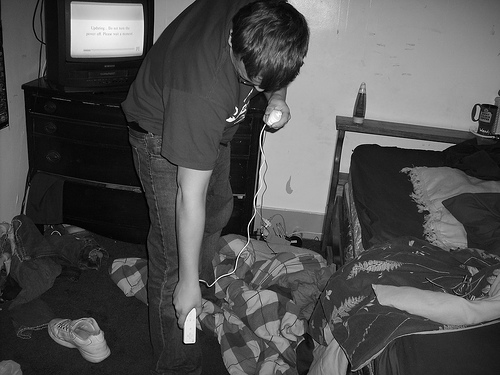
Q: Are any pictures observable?
A: No, there are no pictures.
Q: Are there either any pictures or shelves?
A: No, there are no pictures or shelves.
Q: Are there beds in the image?
A: Yes, there is a bed.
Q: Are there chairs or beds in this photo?
A: Yes, there is a bed.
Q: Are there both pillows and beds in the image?
A: Yes, there are both a bed and a pillow.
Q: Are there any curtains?
A: No, there are no curtains.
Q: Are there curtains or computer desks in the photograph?
A: No, there are no curtains or computer desks.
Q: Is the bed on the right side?
A: Yes, the bed is on the right of the image.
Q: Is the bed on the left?
A: No, the bed is on the right of the image.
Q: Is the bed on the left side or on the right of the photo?
A: The bed is on the right of the image.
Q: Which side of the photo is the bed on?
A: The bed is on the right of the image.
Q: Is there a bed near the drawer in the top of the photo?
A: Yes, there is a bed near the drawer.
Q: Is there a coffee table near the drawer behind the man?
A: No, there is a bed near the drawer.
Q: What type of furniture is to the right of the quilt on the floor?
A: The piece of furniture is a bed.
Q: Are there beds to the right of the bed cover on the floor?
A: Yes, there is a bed to the right of the comforter.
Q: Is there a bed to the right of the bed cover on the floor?
A: Yes, there is a bed to the right of the comforter.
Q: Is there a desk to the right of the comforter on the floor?
A: No, there is a bed to the right of the comforter.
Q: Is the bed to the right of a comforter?
A: Yes, the bed is to the right of a comforter.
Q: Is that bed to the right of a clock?
A: No, the bed is to the right of a comforter.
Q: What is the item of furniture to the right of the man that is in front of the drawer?
A: The piece of furniture is a bed.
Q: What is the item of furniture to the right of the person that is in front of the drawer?
A: The piece of furniture is a bed.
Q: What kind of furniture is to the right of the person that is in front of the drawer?
A: The piece of furniture is a bed.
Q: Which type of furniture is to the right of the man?
A: The piece of furniture is a bed.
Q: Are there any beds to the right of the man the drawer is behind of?
A: Yes, there is a bed to the right of the man.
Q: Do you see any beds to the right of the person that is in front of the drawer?
A: Yes, there is a bed to the right of the man.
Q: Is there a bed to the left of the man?
A: No, the bed is to the right of the man.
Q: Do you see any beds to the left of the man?
A: No, the bed is to the right of the man.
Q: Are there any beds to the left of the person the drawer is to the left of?
A: No, the bed is to the right of the man.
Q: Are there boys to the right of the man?
A: No, there is a bed to the right of the man.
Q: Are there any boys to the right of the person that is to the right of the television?
A: No, there is a bed to the right of the man.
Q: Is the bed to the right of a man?
A: Yes, the bed is to the right of a man.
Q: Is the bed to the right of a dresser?
A: No, the bed is to the right of a man.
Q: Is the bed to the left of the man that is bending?
A: No, the bed is to the right of the man.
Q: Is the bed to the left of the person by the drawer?
A: No, the bed is to the right of the man.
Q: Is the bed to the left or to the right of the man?
A: The bed is to the right of the man.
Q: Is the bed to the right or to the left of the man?
A: The bed is to the right of the man.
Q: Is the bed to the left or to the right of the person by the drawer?
A: The bed is to the right of the man.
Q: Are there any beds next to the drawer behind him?
A: Yes, there is a bed next to the drawer.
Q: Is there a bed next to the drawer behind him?
A: Yes, there is a bed next to the drawer.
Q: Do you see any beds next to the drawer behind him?
A: Yes, there is a bed next to the drawer.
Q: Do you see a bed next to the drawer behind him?
A: Yes, there is a bed next to the drawer.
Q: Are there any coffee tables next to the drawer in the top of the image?
A: No, there is a bed next to the drawer.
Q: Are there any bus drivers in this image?
A: No, there are no bus drivers.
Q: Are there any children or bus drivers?
A: No, there are no bus drivers or children.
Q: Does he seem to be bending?
A: Yes, the man is bending.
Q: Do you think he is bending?
A: Yes, the man is bending.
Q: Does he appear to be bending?
A: Yes, the man is bending.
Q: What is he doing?
A: The man is bending.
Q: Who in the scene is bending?
A: The man is bending.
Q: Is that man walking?
A: No, the man is bending.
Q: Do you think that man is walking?
A: No, the man is bending.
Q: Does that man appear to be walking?
A: No, the man is bending.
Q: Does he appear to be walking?
A: No, the man is bending.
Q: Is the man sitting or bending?
A: The man is bending.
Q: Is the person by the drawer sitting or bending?
A: The man is bending.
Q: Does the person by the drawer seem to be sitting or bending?
A: The man is bending.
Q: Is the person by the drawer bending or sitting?
A: The man is bending.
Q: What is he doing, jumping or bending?
A: The man is bending.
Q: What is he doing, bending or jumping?
A: The man is bending.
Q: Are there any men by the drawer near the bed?
A: Yes, there is a man by the drawer.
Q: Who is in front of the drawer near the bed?
A: The man is in front of the drawer.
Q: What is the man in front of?
A: The man is in front of the drawer.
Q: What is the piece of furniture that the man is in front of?
A: The piece of furniture is a drawer.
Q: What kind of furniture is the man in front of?
A: The man is in front of the drawer.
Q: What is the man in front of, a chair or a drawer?
A: The man is in front of a drawer.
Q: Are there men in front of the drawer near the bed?
A: Yes, there is a man in front of the drawer.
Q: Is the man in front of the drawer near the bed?
A: Yes, the man is in front of the drawer.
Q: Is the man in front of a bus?
A: No, the man is in front of the drawer.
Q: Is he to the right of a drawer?
A: Yes, the man is to the right of a drawer.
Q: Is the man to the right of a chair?
A: No, the man is to the right of a drawer.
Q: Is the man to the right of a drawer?
A: Yes, the man is to the right of a drawer.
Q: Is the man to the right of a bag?
A: No, the man is to the right of a drawer.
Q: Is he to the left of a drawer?
A: No, the man is to the right of a drawer.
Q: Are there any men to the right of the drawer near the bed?
A: Yes, there is a man to the right of the drawer.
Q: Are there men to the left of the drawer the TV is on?
A: No, the man is to the right of the drawer.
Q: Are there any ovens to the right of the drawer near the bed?
A: No, there is a man to the right of the drawer.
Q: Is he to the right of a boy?
A: No, the man is to the right of a drawer.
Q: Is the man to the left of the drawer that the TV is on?
A: No, the man is to the right of the drawer.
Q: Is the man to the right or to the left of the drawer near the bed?
A: The man is to the right of the drawer.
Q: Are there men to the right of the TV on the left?
A: Yes, there is a man to the right of the TV.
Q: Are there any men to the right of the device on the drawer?
A: Yes, there is a man to the right of the TV.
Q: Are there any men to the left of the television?
A: No, the man is to the right of the television.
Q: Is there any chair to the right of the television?
A: No, there is a man to the right of the television.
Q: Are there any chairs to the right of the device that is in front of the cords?
A: No, there is a man to the right of the television.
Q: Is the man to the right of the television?
A: Yes, the man is to the right of the television.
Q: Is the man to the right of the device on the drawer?
A: Yes, the man is to the right of the television.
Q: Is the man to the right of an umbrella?
A: No, the man is to the right of the television.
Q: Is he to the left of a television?
A: No, the man is to the right of a television.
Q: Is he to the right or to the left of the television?
A: The man is to the right of the television.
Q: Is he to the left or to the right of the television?
A: The man is to the right of the television.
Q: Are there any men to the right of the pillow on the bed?
A: No, the man is to the left of the pillow.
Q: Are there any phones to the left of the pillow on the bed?
A: No, there is a man to the left of the pillow.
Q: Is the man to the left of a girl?
A: No, the man is to the left of the pillow.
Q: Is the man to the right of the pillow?
A: No, the man is to the left of the pillow.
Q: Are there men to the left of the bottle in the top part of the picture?
A: Yes, there is a man to the left of the bottle.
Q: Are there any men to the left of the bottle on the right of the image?
A: Yes, there is a man to the left of the bottle.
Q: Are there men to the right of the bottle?
A: No, the man is to the left of the bottle.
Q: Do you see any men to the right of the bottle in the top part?
A: No, the man is to the left of the bottle.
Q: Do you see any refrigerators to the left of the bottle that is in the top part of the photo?
A: No, there is a man to the left of the bottle.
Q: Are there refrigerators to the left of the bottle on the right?
A: No, there is a man to the left of the bottle.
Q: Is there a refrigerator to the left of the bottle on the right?
A: No, there is a man to the left of the bottle.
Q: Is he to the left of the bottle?
A: Yes, the man is to the left of the bottle.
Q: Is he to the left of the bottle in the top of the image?
A: Yes, the man is to the left of the bottle.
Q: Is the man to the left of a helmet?
A: No, the man is to the left of the bottle.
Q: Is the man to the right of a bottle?
A: No, the man is to the left of a bottle.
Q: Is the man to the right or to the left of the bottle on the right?
A: The man is to the left of the bottle.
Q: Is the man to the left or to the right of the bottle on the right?
A: The man is to the left of the bottle.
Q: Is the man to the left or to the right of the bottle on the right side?
A: The man is to the left of the bottle.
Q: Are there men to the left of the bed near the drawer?
A: Yes, there is a man to the left of the bed.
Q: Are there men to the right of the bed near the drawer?
A: No, the man is to the left of the bed.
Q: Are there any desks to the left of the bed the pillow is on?
A: No, there is a man to the left of the bed.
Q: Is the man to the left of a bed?
A: Yes, the man is to the left of a bed.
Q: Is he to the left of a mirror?
A: No, the man is to the left of a bed.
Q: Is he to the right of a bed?
A: No, the man is to the left of a bed.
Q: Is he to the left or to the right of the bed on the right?
A: The man is to the left of the bed.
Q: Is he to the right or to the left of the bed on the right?
A: The man is to the left of the bed.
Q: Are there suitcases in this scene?
A: No, there are no suitcases.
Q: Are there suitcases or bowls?
A: No, there are no suitcases or bowls.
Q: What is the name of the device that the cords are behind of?
A: The device is a television.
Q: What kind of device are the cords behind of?
A: The cords are behind the television.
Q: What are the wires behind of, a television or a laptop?
A: The wires are behind a television.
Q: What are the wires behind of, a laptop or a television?
A: The wires are behind a television.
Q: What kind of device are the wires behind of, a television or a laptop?
A: The wires are behind a television.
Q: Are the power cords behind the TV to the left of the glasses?
A: Yes, the cords are behind the television.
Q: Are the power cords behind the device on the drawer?
A: Yes, the cords are behind the television.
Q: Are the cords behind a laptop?
A: No, the cords are behind the television.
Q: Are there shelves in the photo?
A: No, there are no shelves.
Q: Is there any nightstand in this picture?
A: No, there are no nightstands.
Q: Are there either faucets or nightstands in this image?
A: No, there are no nightstands or faucets.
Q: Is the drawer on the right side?
A: No, the drawer is on the left of the image.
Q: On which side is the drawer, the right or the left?
A: The drawer is on the left of the image.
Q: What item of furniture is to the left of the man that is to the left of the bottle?
A: The piece of furniture is a drawer.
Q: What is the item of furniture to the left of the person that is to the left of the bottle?
A: The piece of furniture is a drawer.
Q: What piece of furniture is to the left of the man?
A: The piece of furniture is a drawer.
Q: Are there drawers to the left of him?
A: Yes, there is a drawer to the left of the man.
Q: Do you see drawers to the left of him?
A: Yes, there is a drawer to the left of the man.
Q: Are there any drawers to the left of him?
A: Yes, there is a drawer to the left of the man.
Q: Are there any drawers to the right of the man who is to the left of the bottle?
A: No, the drawer is to the left of the man.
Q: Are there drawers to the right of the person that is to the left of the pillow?
A: No, the drawer is to the left of the man.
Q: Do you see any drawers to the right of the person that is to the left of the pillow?
A: No, the drawer is to the left of the man.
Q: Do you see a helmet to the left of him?
A: No, there is a drawer to the left of the man.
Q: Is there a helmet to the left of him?
A: No, there is a drawer to the left of the man.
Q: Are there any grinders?
A: No, there are no grinders.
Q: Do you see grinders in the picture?
A: No, there are no grinders.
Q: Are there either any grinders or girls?
A: No, there are no grinders or girls.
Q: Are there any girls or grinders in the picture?
A: No, there are no grinders or girls.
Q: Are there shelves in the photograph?
A: No, there are no shelves.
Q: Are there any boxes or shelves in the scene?
A: No, there are no shelves or boxes.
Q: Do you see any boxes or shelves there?
A: No, there are no shelves or boxes.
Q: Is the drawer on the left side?
A: Yes, the drawer is on the left of the image.